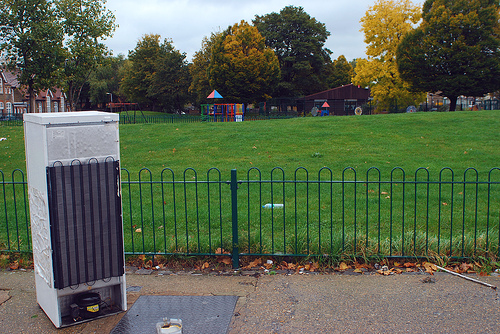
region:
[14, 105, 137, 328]
Refrigerator left sidewalk safety hazard.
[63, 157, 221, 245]
Park fence similar refrigerator coils.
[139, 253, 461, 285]
Wet fall leaves sidewalk gutter.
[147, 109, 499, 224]
Local town recreational park.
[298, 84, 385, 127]
Park club house background.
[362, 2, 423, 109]
Changing golden tree leaves .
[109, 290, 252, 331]
Gray metal plate sidewalk.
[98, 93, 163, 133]
Children's swing set distance.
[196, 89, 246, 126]
Jungle gym children's equipment.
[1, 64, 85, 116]
Large red brick school building.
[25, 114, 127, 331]
a fridge in the street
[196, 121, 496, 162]
a lot of grass in the field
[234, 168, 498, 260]
a green metal fence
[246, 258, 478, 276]
many dry leaves on the ground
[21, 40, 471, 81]
many leafy trees in the background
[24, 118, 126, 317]
the fridge is white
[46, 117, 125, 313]
the rear view of the fridge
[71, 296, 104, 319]
the motor is black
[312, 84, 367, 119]
a brown house in the distance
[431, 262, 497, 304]
a stick on the ground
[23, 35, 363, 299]
a fridge at the park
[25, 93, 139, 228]
the back of a fridge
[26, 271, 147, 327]
the motor of a fridge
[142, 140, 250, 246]
the fencing is black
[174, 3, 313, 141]
the season is fall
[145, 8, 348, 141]
a children's playground in distance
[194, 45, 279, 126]
the umbrella is rainbow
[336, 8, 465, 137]
this tree has yellow leaves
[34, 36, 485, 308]
abandoned fridge at a park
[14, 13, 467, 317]
fridge is trash on sidewalk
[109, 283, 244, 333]
metal plate on a sidewalk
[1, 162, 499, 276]
green metal fence near the sidewalk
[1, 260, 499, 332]
wet cement sidewalk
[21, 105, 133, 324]
discarded refridgerator on the sidewalk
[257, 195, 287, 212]
water bottle on the grass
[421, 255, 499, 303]
stick on the sidewalk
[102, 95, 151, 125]
swing set on the playground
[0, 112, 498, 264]
large grassy play area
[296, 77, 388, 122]
brown wooden building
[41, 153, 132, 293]
coils on the back of a refridgerator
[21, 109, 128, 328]
a refrigerator on a side wall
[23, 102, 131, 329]
a refrigerator in the rain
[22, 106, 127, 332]
a white refrigerator sitting out side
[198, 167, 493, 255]
a black iron railing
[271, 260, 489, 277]
brown leaves on the sidewalk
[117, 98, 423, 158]
a grassy play ground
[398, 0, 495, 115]
a leafy green tree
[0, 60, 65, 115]
a brown and white brick house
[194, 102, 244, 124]
a child's play set